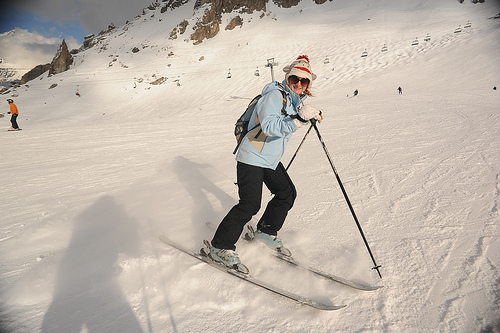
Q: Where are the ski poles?
A: In the woman's hands.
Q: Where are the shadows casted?
A: On the snow.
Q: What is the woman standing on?
A: Ski poles.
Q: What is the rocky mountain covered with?
A: Snow.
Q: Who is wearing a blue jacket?
A: A woman.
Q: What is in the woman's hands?
A: Two black snow poles.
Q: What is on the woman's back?
A: A backpack.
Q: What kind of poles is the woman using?
A: Ski poles.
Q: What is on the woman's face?
A: Sunglasses.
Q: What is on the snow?
A: A shadow.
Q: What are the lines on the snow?
A: Tracks.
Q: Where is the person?
A: On a snowy mountain.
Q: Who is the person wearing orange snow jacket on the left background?
A: Another skier.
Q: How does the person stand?
A: With the person's legs slightly bent.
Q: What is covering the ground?
A: Snow.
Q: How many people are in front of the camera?
A: 1.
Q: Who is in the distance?
A: Other skiers.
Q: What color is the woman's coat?
A: Blue.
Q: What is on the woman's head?
A: A hat.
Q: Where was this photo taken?
A: Outside on a hill.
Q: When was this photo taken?
A: During the day.